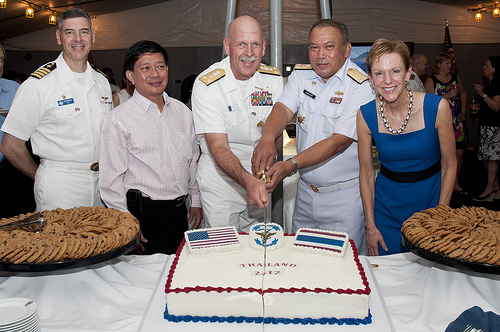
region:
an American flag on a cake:
[185, 225, 241, 254]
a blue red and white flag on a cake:
[293, 227, 348, 257]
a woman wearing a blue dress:
[358, 38, 453, 258]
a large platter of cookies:
[403, 204, 498, 267]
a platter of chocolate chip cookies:
[1, 205, 139, 274]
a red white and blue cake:
[164, 223, 373, 327]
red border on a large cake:
[166, 237, 371, 297]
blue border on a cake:
[163, 310, 372, 324]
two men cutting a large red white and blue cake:
[166, 17, 378, 326]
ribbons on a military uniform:
[248, 89, 273, 106]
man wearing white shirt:
[10, 6, 97, 177]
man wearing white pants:
[10, 10, 91, 201]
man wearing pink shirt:
[115, 36, 205, 206]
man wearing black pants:
[120, 45, 190, 210]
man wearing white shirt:
[205, 10, 270, 120]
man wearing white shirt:
[290, 15, 355, 145]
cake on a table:
[141, 220, 386, 322]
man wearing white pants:
[290, 20, 356, 215]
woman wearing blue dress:
[350, 45, 440, 205]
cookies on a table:
[6, 203, 138, 258]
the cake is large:
[168, 219, 365, 311]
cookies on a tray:
[7, 218, 122, 264]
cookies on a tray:
[405, 217, 480, 269]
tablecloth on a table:
[77, 295, 129, 325]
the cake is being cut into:
[256, 237, 272, 297]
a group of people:
[60, 18, 469, 172]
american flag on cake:
[179, 230, 239, 253]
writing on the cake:
[238, 257, 293, 284]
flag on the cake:
[284, 220, 354, 266]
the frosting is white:
[321, 266, 353, 278]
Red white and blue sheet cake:
[147, 225, 393, 330]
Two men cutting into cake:
[180, 6, 385, 262]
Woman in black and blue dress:
[354, 41, 459, 261]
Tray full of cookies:
[5, 202, 148, 272]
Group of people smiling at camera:
[6, 9, 467, 256]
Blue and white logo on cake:
[245, 214, 285, 251]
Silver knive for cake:
[251, 158, 280, 275]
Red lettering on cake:
[242, 253, 299, 283]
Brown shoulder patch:
[195, 63, 221, 95]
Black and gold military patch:
[29, 53, 59, 88]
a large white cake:
[157, 214, 384, 325]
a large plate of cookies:
[395, 193, 497, 277]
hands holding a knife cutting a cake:
[238, 146, 306, 262]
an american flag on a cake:
[173, 216, 247, 261]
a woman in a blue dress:
[350, 33, 474, 254]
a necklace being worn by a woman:
[372, 84, 426, 137]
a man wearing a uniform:
[10, 8, 132, 215]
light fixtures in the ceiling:
[18, 6, 62, 28]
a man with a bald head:
[214, 11, 279, 86]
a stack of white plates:
[7, 296, 42, 325]